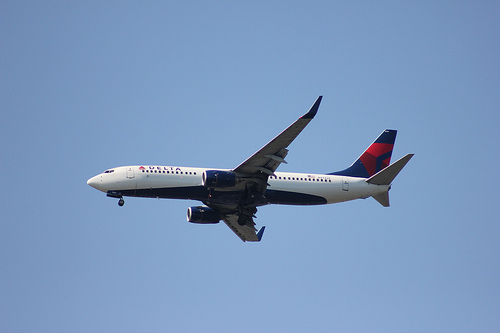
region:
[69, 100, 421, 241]
white plane in sky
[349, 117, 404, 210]
blue and red tail of airplane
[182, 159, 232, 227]
two engines of airplane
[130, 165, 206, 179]
windows on an airplane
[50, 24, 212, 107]
clear blue sky with no clouds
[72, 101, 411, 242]
plane flying in sky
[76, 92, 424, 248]
closeup shot of airplane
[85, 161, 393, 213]
white airplane with blue and red tail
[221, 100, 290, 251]
two wings of airplane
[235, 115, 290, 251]
underside of airplane wings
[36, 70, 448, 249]
Airplane flying in the sky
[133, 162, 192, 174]
The words Delta on the airplane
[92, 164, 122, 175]
Windshield on the airplane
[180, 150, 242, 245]
Engines on the airplane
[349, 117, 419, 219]
Tail of the airplane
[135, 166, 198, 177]
Windows on an airplane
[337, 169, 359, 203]
Door on an airplane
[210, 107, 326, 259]
Underside of the wings on an airplane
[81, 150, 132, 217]
Nose of an airplane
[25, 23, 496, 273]
No clouds in the blue sky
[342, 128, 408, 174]
blue and red airplane tail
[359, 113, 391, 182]
blue and red airplane tail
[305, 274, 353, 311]
the sky is so clear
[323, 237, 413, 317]
the sky is so clear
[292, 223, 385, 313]
the sky is so clear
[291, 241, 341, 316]
the sky is so clear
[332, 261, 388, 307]
the sky is so clear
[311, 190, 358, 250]
the sky is so clear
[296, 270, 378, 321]
the sky is so clear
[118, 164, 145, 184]
front door near front of plane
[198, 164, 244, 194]
engine in front of the picture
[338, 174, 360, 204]
passenger exit door in rear of plane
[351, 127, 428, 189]
red and blue decor on tail of plane wing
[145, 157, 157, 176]
letter d on side of plane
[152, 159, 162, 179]
letter e on side of plane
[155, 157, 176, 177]
letter l on side of plane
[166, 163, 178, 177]
letter t on side of plane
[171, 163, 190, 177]
letter a on side of plane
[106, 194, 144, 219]
front wheel at begining of plane